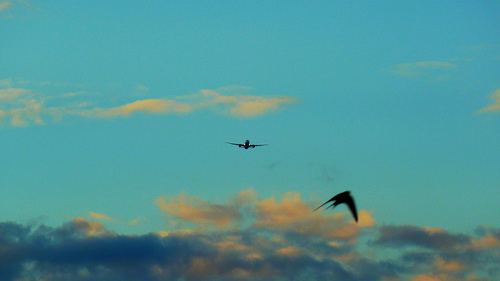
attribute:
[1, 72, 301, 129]
cloud — white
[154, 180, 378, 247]
cloud — white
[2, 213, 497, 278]
cloud — white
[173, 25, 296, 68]
sky — turquoise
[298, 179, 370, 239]
bird — black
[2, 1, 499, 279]
sky — blue, bright blue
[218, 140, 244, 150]
wing — thin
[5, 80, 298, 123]
cloud — thin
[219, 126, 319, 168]
plane — flying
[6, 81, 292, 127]
clouds — white